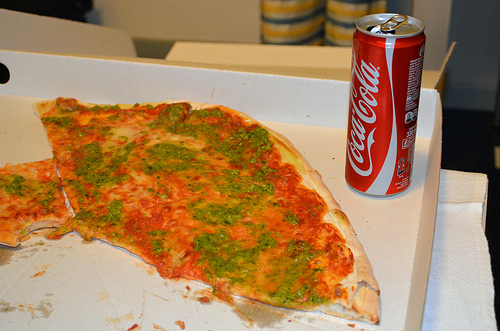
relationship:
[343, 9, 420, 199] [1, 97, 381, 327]
can near pizza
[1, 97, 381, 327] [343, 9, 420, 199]
pizza near can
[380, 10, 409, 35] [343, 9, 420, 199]
top of can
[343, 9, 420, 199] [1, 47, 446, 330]
can sitting on box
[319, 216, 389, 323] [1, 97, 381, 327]
crust of a pizza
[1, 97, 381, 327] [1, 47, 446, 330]
pizza inside a box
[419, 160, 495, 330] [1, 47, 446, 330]
towel under a box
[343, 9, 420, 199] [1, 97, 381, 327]
can beside pizza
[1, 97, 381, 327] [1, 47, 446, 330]
pizza laying on box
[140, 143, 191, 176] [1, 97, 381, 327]
herbs on top of pizza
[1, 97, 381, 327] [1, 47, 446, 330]
pizza inside box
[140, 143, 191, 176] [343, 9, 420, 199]
herbs near can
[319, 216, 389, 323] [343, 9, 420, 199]
crust near can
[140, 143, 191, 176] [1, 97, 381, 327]
herbs on pizza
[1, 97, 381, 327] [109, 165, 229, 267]
pizza with cheese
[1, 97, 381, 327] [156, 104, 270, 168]
pizza with pesto